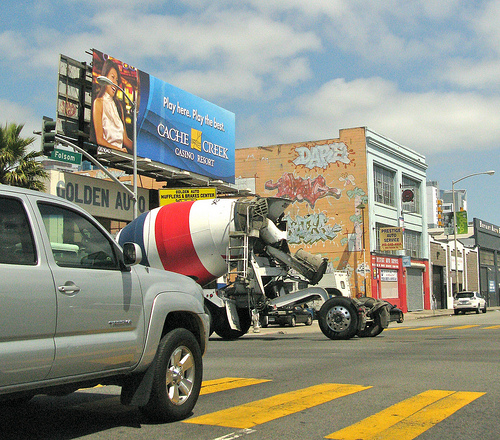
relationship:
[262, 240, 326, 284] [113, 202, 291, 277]
chute connected to mixer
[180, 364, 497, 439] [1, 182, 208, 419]
crosswalk under truck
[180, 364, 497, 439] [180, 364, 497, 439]
crosswalk on crosswalk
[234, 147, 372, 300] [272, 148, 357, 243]
wall has graffiti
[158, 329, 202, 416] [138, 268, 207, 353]
tire on front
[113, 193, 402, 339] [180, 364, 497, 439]
cement mixer on crosswalk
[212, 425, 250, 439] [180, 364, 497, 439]
line painted on crosswalk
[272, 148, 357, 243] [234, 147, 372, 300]
graffiti on wall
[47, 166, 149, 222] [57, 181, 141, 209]
sign has writing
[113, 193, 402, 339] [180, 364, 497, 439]
mixer on crosswalk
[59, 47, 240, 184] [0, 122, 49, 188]
billboard in front of tree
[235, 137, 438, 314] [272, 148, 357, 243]
building has graffiti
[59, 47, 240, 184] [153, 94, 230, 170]
billboard has writing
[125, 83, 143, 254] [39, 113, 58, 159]
pole has stoplight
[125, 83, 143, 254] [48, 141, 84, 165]
pole has a sign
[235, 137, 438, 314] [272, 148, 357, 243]
building has writing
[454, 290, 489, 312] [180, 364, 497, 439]
car on crosswalk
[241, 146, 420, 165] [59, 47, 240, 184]
roof has board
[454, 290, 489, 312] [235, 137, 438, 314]
car in front of building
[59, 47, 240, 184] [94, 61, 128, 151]
board has a woman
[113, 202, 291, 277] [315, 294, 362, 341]
mixer has wheels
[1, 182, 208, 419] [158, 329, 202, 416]
car has wheels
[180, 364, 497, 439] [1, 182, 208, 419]
crosswalk has vehicle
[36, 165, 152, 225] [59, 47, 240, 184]
building has advertisement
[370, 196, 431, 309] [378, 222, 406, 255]
wall has sign